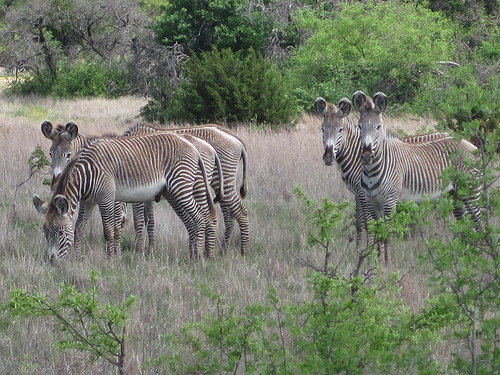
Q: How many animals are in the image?
A: Five.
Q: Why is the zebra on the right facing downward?
A: Eating.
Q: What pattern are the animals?
A: Striped.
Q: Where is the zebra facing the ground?
A: On the left.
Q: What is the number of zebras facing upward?
A: Three.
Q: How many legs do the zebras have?
A: Four.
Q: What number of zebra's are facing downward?
A: Two.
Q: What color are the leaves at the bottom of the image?
A: Green.